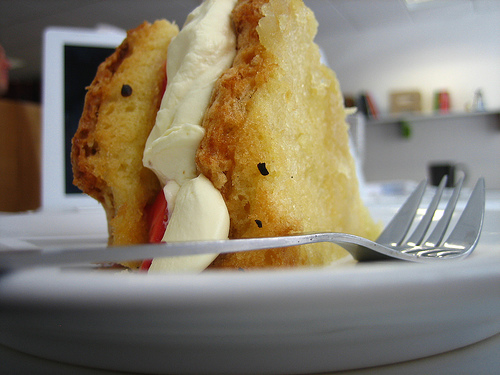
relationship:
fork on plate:
[0, 175, 486, 294] [1, 199, 500, 375]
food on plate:
[70, 0, 385, 270] [1, 199, 500, 375]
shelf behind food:
[365, 109, 500, 124] [70, 0, 385, 270]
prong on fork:
[442, 176, 487, 259] [0, 175, 486, 294]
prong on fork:
[423, 176, 464, 247] [0, 175, 486, 294]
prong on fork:
[402, 173, 450, 247] [0, 175, 486, 294]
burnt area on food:
[121, 83, 133, 98] [70, 0, 385, 270]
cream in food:
[142, 0, 237, 275] [70, 0, 385, 270]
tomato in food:
[135, 190, 169, 272] [70, 0, 385, 270]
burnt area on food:
[257, 162, 270, 177] [70, 0, 385, 270]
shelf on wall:
[365, 109, 500, 124] [314, 15, 500, 193]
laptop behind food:
[43, 28, 127, 234] [70, 0, 385, 270]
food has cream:
[70, 0, 385, 270] [142, 0, 237, 275]